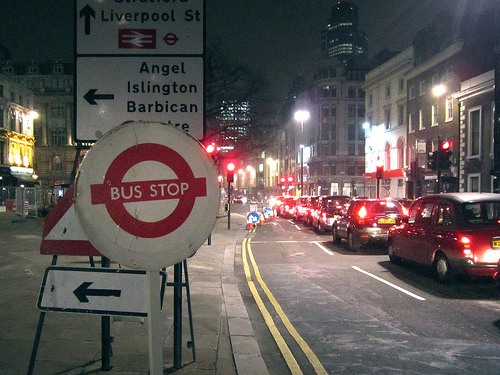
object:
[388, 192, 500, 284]
cars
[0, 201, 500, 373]
road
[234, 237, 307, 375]
lines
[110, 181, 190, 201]
bus stop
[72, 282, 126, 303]
arrow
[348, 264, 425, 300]
line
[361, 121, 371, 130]
lights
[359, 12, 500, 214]
building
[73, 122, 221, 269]
sign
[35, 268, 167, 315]
sign